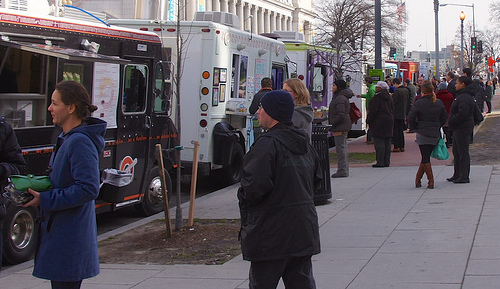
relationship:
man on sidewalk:
[241, 93, 328, 289] [358, 188, 491, 285]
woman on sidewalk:
[31, 87, 115, 283] [358, 188, 491, 285]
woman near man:
[31, 87, 115, 283] [241, 93, 328, 289]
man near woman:
[241, 93, 328, 289] [31, 87, 115, 283]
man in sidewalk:
[241, 93, 328, 289] [358, 188, 491, 285]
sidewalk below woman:
[358, 188, 491, 285] [31, 87, 115, 283]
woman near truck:
[31, 87, 115, 283] [88, 29, 191, 217]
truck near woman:
[88, 29, 191, 217] [31, 87, 115, 283]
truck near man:
[88, 29, 191, 217] [241, 93, 328, 289]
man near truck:
[241, 93, 328, 289] [88, 29, 191, 217]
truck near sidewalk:
[88, 29, 191, 217] [358, 188, 491, 285]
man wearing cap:
[241, 93, 328, 289] [258, 89, 296, 123]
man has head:
[241, 93, 328, 289] [255, 90, 294, 127]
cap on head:
[258, 89, 296, 123] [255, 90, 294, 127]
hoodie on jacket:
[265, 123, 311, 158] [236, 120, 319, 261]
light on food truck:
[202, 87, 210, 95] [107, 18, 297, 183]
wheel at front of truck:
[142, 161, 174, 213] [0, 8, 179, 267]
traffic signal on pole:
[468, 35, 478, 50] [471, 5, 476, 37]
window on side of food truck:
[231, 50, 249, 98] [107, 18, 296, 183]